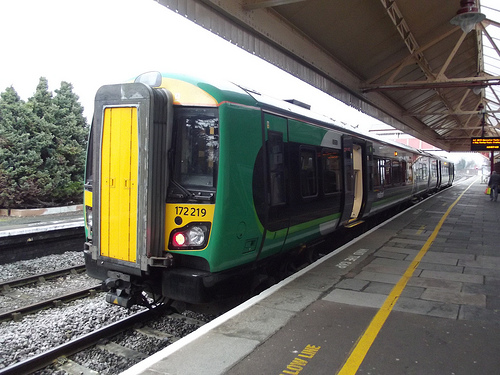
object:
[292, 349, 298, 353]
spot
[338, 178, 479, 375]
line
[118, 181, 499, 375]
platform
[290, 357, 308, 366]
words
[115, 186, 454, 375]
edge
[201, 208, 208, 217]
words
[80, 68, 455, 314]
train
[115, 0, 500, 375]
station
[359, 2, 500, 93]
beams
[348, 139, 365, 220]
door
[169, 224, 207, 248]
light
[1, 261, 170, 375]
tracks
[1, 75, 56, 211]
trees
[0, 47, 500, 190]
background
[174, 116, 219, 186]
window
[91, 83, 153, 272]
door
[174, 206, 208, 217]
numbers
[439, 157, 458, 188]
cars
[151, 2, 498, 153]
overhang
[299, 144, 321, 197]
windows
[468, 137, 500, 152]
sign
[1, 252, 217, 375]
gravel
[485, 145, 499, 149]
writing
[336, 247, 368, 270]
writing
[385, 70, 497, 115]
frame